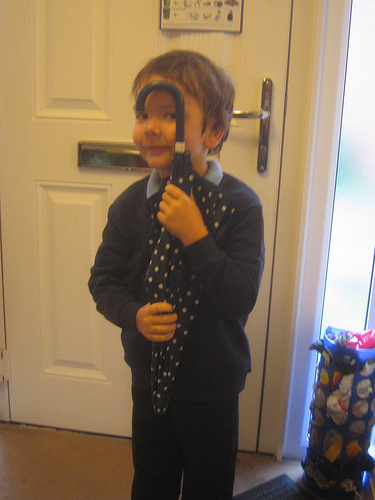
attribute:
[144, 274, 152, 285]
polkadot — white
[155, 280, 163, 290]
polkadot — white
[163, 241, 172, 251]
polkadot — white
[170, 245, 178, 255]
polkadot — white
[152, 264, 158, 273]
polkadot — white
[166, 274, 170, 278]
polkadot — white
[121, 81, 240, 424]
umbrella — white, polka dot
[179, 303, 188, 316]
polkadot — white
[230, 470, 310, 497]
rug — black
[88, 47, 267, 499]
boy — young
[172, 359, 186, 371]
polka dot — white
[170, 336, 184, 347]
polka dot — white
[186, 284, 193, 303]
polka dot — white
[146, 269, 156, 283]
polka dot — white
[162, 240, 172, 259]
polka dot — white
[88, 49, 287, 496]
child — young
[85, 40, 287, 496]
boy — young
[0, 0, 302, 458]
door — white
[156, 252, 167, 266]
dot — white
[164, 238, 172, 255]
dot — white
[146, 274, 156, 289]
dot — white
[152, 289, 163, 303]
dot — white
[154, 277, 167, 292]
dot — white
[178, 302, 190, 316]
dot — white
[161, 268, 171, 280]
dot — white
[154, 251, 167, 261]
dot — white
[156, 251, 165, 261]
dot — white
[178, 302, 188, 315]
dot — white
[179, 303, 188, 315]
dot — white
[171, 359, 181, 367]
dot — white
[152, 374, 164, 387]
dot — white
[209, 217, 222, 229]
dot — white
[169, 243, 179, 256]
dot — white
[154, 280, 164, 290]
dot — white